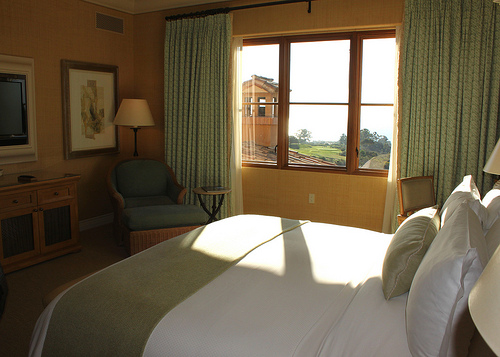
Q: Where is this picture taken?
A: In a bedroom.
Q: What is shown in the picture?
A: A bed.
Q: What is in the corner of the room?
A: A Chair.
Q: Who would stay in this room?
A: Travelers.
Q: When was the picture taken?
A: In the daytime.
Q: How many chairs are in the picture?
A: Two.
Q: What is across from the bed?
A: A TV.